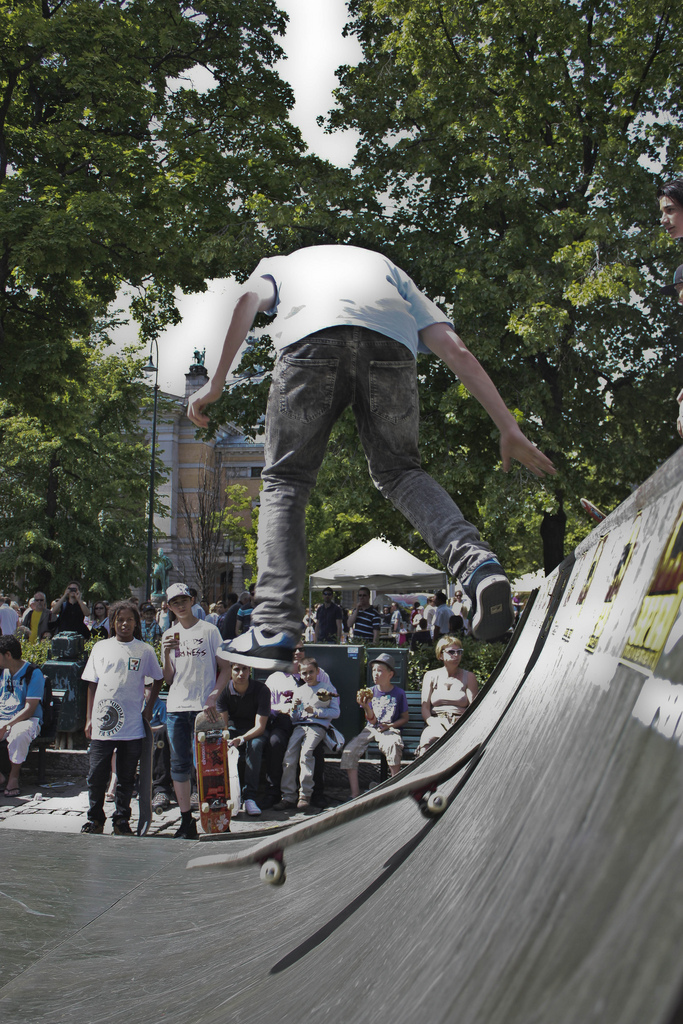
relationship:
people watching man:
[89, 586, 221, 781] [234, 227, 504, 593]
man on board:
[234, 227, 504, 593] [221, 766, 473, 889]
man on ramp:
[234, 227, 504, 593] [566, 549, 660, 925]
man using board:
[234, 227, 504, 593] [221, 766, 473, 889]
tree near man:
[382, 37, 634, 219] [234, 227, 504, 593]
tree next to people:
[382, 37, 634, 219] [89, 586, 221, 781]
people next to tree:
[89, 586, 221, 781] [382, 37, 634, 219]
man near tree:
[234, 227, 504, 593] [382, 37, 634, 219]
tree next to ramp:
[382, 37, 634, 219] [566, 549, 660, 925]